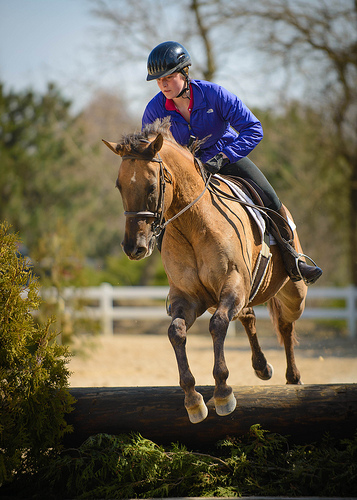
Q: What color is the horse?
A: Brown.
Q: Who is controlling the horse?
A: The rider.